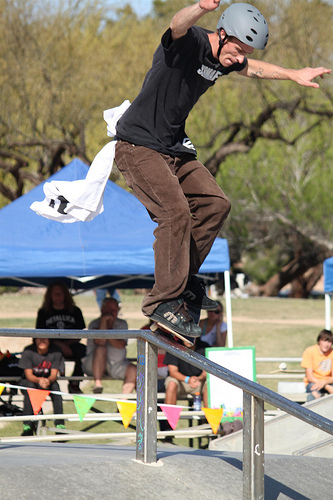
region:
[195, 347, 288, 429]
A pole on the ramp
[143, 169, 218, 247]
Brown pants in the photo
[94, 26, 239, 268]
A young man skating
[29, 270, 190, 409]
People watching in the background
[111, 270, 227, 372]
skateboard over highest slanting part of railing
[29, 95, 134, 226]
white shirt tucked into back waist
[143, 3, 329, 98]
skateboarder with arms lifted out to side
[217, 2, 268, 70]
head in helmet while looking down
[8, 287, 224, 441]
spectators looking ahead at railing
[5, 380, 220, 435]
colorful flags on white line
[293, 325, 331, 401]
spectator sitting in sun looking up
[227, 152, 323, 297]
collapsed brown structure in background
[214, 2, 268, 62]
grey helmet with a black chin strap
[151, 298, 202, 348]
black textured wooden skateboard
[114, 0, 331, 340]
teenager doing a skateboard trick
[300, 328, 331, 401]
teenager watching the skateboarders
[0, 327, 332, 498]
silver metal grinding rail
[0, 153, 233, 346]
blue tent with white poles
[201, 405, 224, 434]
yellow plastic flag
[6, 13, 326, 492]
a scene during the day time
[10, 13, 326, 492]
a scene outside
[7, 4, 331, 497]
a scene at a park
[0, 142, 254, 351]
a blue tent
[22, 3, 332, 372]
a skateboarder doing a trick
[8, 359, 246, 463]
a colorful banner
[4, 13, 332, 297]
some green trees in the background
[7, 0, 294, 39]
a blue sky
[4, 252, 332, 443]
a group of people watching the skateboarder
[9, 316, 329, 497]
a gray guardrail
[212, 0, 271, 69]
grey helmet on skateboarder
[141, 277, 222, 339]
pair of black and tan sneakers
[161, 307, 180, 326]
tan adidas logo on black sneaker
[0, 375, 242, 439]
line of upside down flags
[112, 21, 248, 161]
black and white cotton t-shirt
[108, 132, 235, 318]
brown pants on skateboarder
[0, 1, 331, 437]
skateboarder skateboarding on metal hhand rail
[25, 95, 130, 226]
white rag hanging out of skateboarders back pocket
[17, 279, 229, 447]
people sitting on bleachers watching skateboarder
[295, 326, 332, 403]
boy in orange shirt watching skateboarder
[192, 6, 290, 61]
boy has grey helmet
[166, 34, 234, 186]
black and white shirt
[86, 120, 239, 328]
boy has brown pants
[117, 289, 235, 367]
black and brown shoes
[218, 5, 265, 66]
head of a person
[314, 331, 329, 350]
head of a person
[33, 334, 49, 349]
head of a person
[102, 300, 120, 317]
head of a person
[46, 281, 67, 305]
head of a person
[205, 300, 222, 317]
head of a person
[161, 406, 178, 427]
the flag is pink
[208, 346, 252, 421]
white and green sign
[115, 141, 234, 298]
the pants are brown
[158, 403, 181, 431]
the triangle is pink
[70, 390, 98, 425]
the triangle is green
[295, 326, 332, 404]
man wearing orange shirt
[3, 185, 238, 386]
people is under an awning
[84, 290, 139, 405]
man sits on a bench